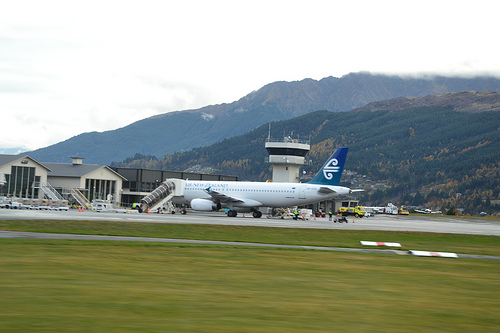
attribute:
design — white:
[323, 157, 340, 178]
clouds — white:
[2, 40, 139, 106]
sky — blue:
[1, 13, 499, 60]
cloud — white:
[22, 97, 37, 110]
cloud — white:
[74, 79, 110, 117]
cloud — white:
[145, 53, 192, 92]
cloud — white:
[240, 28, 291, 48]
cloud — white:
[313, 18, 381, 55]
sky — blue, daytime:
[0, 0, 497, 154]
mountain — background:
[111, 91, 498, 216]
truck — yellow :
[336, 199, 366, 216]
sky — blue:
[1, 19, 493, 154]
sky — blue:
[166, 39, 348, 91]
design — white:
[324, 153, 341, 180]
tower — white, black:
[264, 140, 311, 184]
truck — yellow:
[333, 198, 367, 220]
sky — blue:
[28, 26, 156, 108]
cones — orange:
[43, 177, 405, 217]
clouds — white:
[1, 4, 496, 155]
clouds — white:
[2, 46, 205, 111]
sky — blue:
[1, 0, 495, 100]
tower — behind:
[261, 132, 313, 184]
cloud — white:
[2, 31, 87, 61]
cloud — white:
[132, 67, 217, 109]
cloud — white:
[107, 92, 184, 120]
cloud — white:
[8, 105, 86, 137]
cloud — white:
[77, 102, 127, 132]